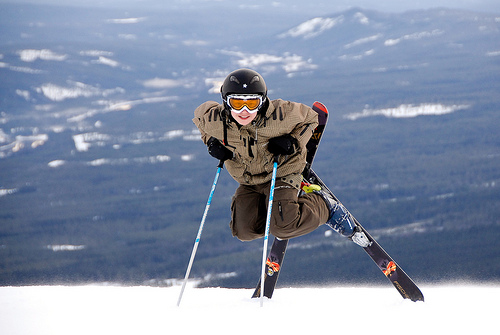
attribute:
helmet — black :
[222, 67, 267, 96]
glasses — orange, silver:
[222, 92, 264, 114]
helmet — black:
[217, 72, 275, 129]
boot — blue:
[315, 190, 360, 240]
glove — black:
[264, 130, 309, 170]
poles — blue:
[162, 135, 344, 296]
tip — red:
[310, 98, 334, 119]